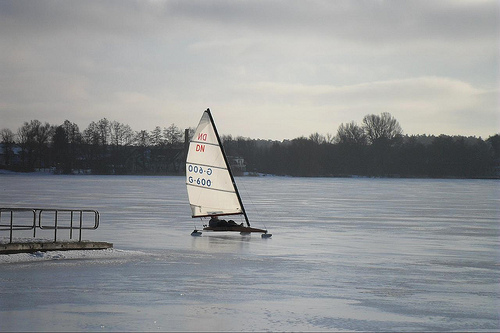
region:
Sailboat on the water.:
[187, 108, 273, 240]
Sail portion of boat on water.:
[185, 108, 246, 218]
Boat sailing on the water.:
[192, 221, 272, 237]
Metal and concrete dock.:
[1, 204, 151, 264]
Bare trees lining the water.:
[73, 119, 176, 174]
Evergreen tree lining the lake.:
[49, 124, 74, 175]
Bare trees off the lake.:
[89, 117, 177, 176]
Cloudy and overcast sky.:
[273, 18, 494, 112]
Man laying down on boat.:
[209, 210, 242, 230]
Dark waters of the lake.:
[285, 198, 492, 309]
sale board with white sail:
[172, 103, 284, 248]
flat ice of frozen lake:
[293, 200, 448, 318]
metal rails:
[6, 192, 108, 242]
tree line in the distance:
[334, 114, 430, 171]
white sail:
[180, 113, 250, 217]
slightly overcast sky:
[263, 42, 433, 97]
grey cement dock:
[22, 242, 120, 258]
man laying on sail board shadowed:
[205, 206, 260, 236]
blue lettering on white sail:
[180, 158, 216, 189]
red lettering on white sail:
[192, 125, 214, 160]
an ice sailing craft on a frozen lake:
[1, 0, 498, 332]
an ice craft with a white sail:
[186, 107, 246, 217]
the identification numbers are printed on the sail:
[187, 164, 214, 186]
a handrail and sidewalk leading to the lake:
[0, 205, 112, 250]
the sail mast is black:
[204, 108, 254, 227]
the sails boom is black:
[191, 208, 241, 218]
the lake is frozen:
[1, 172, 498, 332]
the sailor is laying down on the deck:
[208, 213, 243, 228]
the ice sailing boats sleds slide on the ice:
[261, 231, 273, 239]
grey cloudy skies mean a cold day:
[1, 0, 498, 137]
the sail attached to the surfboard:
[176, 105, 247, 219]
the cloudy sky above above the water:
[3, 2, 499, 137]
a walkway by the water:
[6, 204, 116, 259]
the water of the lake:
[6, 175, 494, 329]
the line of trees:
[6, 118, 498, 170]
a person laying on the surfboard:
[199, 210, 251, 231]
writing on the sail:
[185, 161, 215, 186]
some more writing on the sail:
[189, 132, 211, 154]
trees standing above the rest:
[338, 112, 398, 141]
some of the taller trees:
[5, 120, 193, 142]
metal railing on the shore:
[0, 206, 102, 248]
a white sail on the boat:
[181, 107, 248, 219]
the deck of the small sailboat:
[187, 211, 274, 241]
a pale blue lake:
[1, 170, 498, 331]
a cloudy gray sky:
[0, 0, 499, 141]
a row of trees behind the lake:
[0, 109, 499, 179]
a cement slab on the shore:
[0, 233, 115, 254]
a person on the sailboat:
[207, 210, 245, 229]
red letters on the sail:
[193, 129, 210, 154]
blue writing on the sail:
[186, 163, 214, 188]